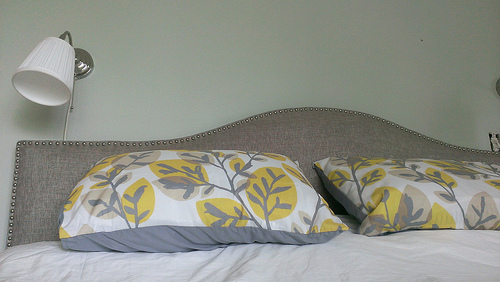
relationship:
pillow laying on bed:
[59, 149, 350, 253] [0, 108, 498, 281]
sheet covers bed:
[0, 213, 499, 281] [0, 108, 498, 281]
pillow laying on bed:
[312, 155, 499, 236] [0, 108, 498, 281]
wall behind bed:
[1, 0, 500, 251] [0, 108, 498, 281]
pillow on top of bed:
[59, 149, 350, 253] [0, 108, 498, 281]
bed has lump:
[0, 108, 498, 281] [189, 244, 266, 281]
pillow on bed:
[312, 155, 499, 236] [0, 108, 498, 281]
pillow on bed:
[59, 149, 350, 253] [0, 108, 498, 281]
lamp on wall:
[11, 31, 94, 140] [1, 0, 500, 251]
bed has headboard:
[0, 108, 498, 281] [5, 107, 498, 241]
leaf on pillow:
[120, 177, 155, 224] [59, 149, 350, 253]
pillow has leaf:
[59, 149, 350, 253] [120, 177, 155, 224]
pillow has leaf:
[312, 155, 499, 236] [360, 167, 386, 187]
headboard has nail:
[5, 107, 498, 241] [16, 141, 22, 146]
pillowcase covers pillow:
[58, 149, 350, 254] [59, 149, 350, 253]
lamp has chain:
[11, 31, 94, 140] [70, 62, 74, 111]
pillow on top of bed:
[312, 155, 499, 236] [0, 108, 498, 281]